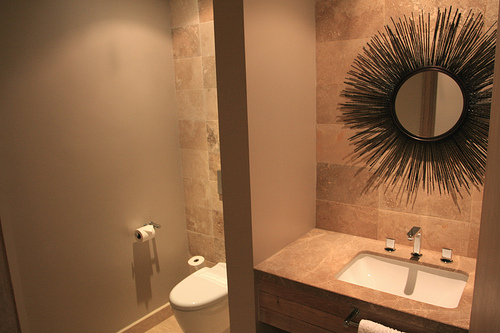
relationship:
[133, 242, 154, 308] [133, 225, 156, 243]
shadow of tp roll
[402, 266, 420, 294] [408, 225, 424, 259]
shadow of faucet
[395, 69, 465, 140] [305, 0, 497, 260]
mirror on wall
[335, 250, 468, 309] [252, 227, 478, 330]
sink in counter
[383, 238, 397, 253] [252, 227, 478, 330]
hot water knob on counter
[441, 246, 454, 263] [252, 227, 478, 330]
cold water knob on counter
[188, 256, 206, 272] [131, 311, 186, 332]
toilet paper roll on ground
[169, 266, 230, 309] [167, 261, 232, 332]
lid on toilet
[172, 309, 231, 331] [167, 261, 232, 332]
bowl for toilet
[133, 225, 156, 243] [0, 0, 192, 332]
tp roll on wall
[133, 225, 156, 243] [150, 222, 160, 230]
tp roll on a holder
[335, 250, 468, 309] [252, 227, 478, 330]
sink mounted in counter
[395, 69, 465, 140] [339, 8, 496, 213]
mirror with frame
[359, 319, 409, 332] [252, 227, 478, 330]
towel on front of counter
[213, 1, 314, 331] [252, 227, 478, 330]
support wall for counter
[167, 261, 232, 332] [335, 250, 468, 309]
toilet and sink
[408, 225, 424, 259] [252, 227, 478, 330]
faucet on counter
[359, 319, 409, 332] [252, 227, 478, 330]
towel on counter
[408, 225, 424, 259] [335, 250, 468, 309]
faucet above sink